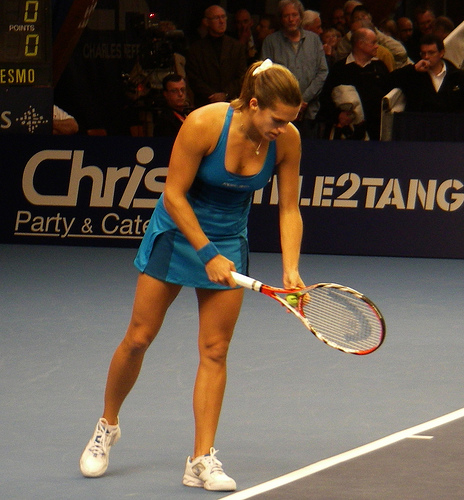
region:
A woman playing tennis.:
[77, 49, 357, 498]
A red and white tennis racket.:
[225, 259, 390, 357]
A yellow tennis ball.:
[286, 286, 311, 307]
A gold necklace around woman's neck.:
[236, 106, 267, 159]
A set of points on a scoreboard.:
[21, 0, 42, 60]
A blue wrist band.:
[190, 237, 227, 260]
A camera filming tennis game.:
[131, 16, 182, 73]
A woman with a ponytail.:
[228, 59, 301, 143]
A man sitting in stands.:
[155, 71, 196, 133]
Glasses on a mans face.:
[418, 50, 439, 58]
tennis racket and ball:
[229, 268, 387, 357]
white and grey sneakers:
[78, 418, 238, 492]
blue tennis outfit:
[133, 105, 278, 290]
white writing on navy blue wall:
[11, 146, 462, 242]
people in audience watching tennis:
[164, 0, 462, 141]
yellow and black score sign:
[0, 0, 53, 85]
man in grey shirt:
[260, 0, 329, 121]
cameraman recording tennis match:
[131, 16, 187, 90]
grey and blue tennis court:
[0, 240, 463, 497]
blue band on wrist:
[194, 239, 220, 267]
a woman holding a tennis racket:
[99, 39, 367, 483]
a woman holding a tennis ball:
[197, 55, 328, 324]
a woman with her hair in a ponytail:
[217, 48, 312, 152]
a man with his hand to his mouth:
[401, 29, 450, 110]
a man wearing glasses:
[165, 63, 191, 114]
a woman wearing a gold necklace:
[178, 61, 308, 184]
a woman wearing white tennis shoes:
[71, 75, 344, 495]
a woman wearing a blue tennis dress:
[140, 60, 326, 306]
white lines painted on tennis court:
[271, 408, 453, 498]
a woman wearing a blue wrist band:
[173, 51, 351, 316]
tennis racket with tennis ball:
[226, 253, 389, 366]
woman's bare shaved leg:
[193, 293, 233, 444]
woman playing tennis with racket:
[130, 50, 393, 376]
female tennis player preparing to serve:
[151, 38, 393, 385]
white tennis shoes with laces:
[171, 446, 241, 492]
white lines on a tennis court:
[285, 389, 449, 472]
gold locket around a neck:
[236, 113, 272, 170]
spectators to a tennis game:
[182, 1, 445, 55]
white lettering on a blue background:
[16, 140, 130, 238]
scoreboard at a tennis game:
[4, 1, 54, 77]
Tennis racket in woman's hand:
[222, 265, 402, 361]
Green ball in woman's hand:
[273, 281, 310, 314]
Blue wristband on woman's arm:
[190, 232, 231, 274]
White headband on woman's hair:
[243, 61, 278, 75]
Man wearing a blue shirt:
[257, 2, 328, 121]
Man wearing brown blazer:
[189, 5, 246, 107]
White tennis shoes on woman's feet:
[77, 399, 242, 495]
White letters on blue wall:
[310, 163, 463, 239]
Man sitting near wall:
[148, 73, 205, 155]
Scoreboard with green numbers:
[0, 0, 53, 143]